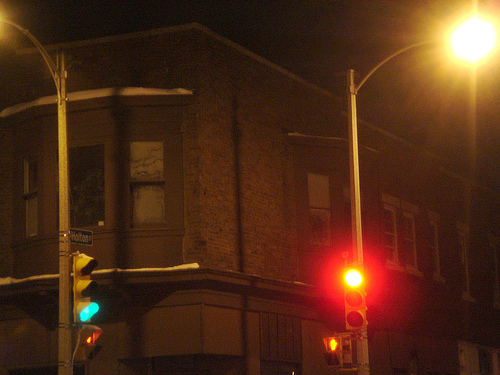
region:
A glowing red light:
[329, 257, 369, 294]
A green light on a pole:
[66, 293, 116, 341]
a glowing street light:
[424, 6, 499, 75]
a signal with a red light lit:
[328, 240, 371, 350]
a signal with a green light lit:
[67, 247, 97, 332]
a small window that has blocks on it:
[114, 125, 192, 235]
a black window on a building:
[50, 129, 121, 234]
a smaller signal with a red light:
[317, 327, 368, 374]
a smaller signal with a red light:
[66, 316, 111, 367]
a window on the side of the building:
[372, 193, 407, 278]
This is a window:
[296, 162, 335, 210]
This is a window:
[123, 134, 169, 179]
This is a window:
[128, 180, 169, 230]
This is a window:
[67, 145, 107, 227]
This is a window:
[18, 150, 40, 193]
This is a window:
[20, 190, 44, 240]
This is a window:
[378, 187, 422, 274]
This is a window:
[425, 203, 445, 280]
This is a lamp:
[330, 252, 375, 305]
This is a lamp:
[418, 4, 499, 99]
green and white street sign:
[35, 210, 125, 256]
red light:
[320, 247, 390, 294]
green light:
[66, 290, 117, 328]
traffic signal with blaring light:
[315, 253, 390, 345]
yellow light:
[356, 33, 496, 59]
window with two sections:
[116, 122, 184, 259]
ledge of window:
[120, 225, 185, 255]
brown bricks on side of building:
[190, 81, 292, 272]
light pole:
[348, 107, 384, 372]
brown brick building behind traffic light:
[31, 61, 307, 369]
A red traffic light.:
[337, 260, 369, 336]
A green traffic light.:
[70, 246, 102, 324]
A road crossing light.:
[320, 335, 340, 357]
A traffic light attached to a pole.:
[340, 65, 365, 365]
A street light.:
[355, 0, 495, 85]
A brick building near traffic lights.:
[5, 37, 492, 368]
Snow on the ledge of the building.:
[0, 250, 200, 282]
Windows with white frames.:
[370, 197, 482, 272]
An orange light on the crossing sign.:
[323, 333, 340, 355]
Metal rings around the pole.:
[55, 226, 72, 371]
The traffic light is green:
[63, 242, 100, 332]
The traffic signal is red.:
[327, 248, 381, 307]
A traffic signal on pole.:
[40, 118, 112, 347]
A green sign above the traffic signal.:
[51, 215, 103, 249]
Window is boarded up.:
[124, 173, 188, 253]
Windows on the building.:
[383, 198, 455, 281]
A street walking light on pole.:
[318, 331, 358, 370]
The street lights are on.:
[372, 20, 489, 72]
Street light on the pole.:
[306, 23, 486, 250]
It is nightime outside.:
[61, 8, 410, 103]